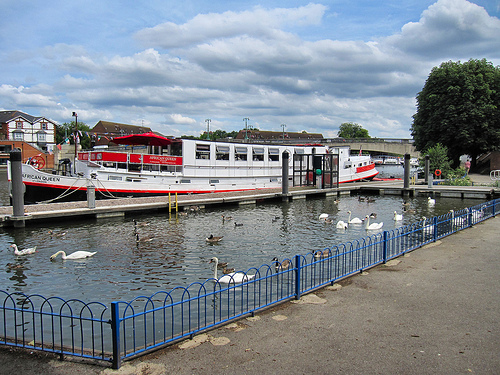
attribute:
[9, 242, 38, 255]
goose — white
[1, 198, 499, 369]
fence — blue, low, metal, rounded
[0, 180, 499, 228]
boat — red, white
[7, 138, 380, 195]
boat — red, white, large, in water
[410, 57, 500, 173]
tree — large, bushy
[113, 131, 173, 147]
canopy — red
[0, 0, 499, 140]
sky — cloudy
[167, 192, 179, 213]
ladder — yellow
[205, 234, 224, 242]
duck — brown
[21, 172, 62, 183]
words — black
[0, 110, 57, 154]
house — white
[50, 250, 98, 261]
swan — white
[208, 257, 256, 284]
swan — white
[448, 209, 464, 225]
swan — white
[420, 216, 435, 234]
swan — white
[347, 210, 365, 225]
swan — white